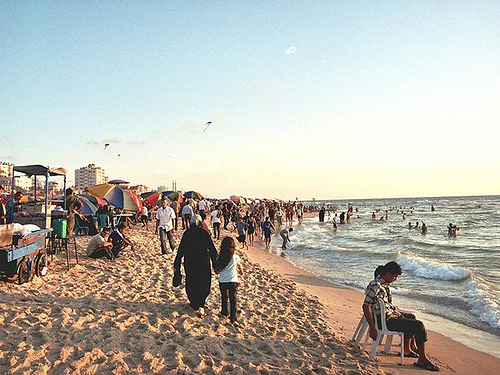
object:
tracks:
[0, 226, 385, 373]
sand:
[2, 322, 314, 374]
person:
[447, 223, 453, 235]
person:
[421, 223, 427, 233]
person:
[431, 205, 435, 212]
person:
[319, 207, 325, 223]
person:
[345, 211, 350, 224]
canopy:
[13, 164, 67, 176]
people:
[318, 203, 460, 237]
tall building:
[0, 161, 59, 189]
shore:
[0, 209, 499, 375]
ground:
[0, 316, 331, 375]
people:
[360, 261, 443, 372]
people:
[261, 216, 275, 248]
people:
[154, 198, 176, 257]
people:
[231, 217, 250, 250]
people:
[87, 228, 116, 261]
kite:
[203, 121, 211, 132]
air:
[5, 7, 489, 367]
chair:
[352, 298, 405, 364]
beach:
[3, 185, 487, 375]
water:
[290, 219, 499, 335]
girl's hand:
[239, 271, 244, 276]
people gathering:
[0, 185, 460, 372]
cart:
[0, 221, 54, 284]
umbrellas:
[162, 191, 185, 204]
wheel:
[18, 258, 32, 284]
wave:
[395, 256, 498, 329]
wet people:
[358, 210, 472, 239]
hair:
[212, 235, 235, 274]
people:
[146, 197, 288, 259]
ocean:
[269, 196, 499, 340]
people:
[172, 213, 243, 326]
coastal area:
[292, 225, 357, 300]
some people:
[208, 198, 302, 248]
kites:
[103, 143, 110, 151]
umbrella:
[87, 183, 145, 212]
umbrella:
[183, 191, 204, 201]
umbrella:
[140, 191, 173, 207]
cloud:
[284, 45, 297, 56]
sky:
[20, 24, 482, 169]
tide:
[264, 197, 498, 335]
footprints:
[0, 224, 378, 375]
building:
[75, 164, 109, 189]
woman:
[172, 214, 219, 315]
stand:
[9, 175, 68, 217]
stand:
[45, 236, 78, 271]